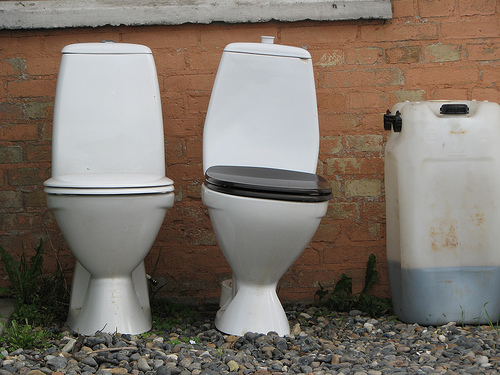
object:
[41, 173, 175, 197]
lid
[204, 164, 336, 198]
lid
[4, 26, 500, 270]
wall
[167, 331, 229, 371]
gravel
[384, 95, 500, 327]
container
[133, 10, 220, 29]
ledge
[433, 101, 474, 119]
cap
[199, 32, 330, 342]
toilet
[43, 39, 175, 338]
toilets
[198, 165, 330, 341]
seat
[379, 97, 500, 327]
jug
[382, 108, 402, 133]
knozzle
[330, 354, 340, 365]
rocks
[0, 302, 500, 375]
ground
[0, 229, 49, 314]
weeds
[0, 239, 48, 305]
plants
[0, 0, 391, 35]
window sill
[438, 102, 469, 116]
stopper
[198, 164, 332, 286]
bowl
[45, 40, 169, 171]
tank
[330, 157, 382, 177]
brick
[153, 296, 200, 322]
grass